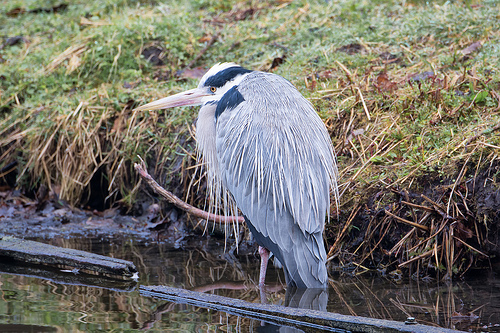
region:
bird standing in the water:
[128, 62, 340, 323]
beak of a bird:
[127, 83, 208, 126]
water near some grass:
[0, 188, 497, 331]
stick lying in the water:
[3, 225, 143, 291]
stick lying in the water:
[142, 277, 428, 332]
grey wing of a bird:
[212, 75, 340, 293]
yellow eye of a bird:
[207, 82, 219, 94]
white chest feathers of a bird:
[178, 101, 248, 256]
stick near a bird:
[133, 154, 246, 235]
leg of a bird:
[247, 243, 279, 288]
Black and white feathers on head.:
[133, 48, 273, 115]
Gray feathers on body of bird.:
[185, 46, 343, 286]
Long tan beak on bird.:
[132, 56, 261, 119]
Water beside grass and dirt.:
[1, 172, 498, 330]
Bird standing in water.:
[130, 54, 347, 306]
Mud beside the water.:
[446, 173, 498, 272]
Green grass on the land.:
[287, 9, 467, 48]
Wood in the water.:
[2, 235, 145, 287]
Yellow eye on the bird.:
[191, 58, 243, 108]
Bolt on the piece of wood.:
[398, 310, 419, 330]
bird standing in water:
[136, 59, 345, 290]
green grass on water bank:
[3, 7, 493, 291]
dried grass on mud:
[337, 169, 486, 279]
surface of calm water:
[5, 234, 498, 329]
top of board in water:
[143, 283, 448, 331]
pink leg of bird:
[253, 244, 272, 287]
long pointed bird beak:
[135, 87, 206, 120]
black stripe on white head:
[203, 62, 247, 89]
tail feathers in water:
[272, 252, 332, 298]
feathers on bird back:
[227, 75, 339, 248]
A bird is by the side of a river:
[65, 35, 456, 320]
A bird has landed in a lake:
[65, 15, 425, 305]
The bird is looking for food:
[65, 31, 426, 306]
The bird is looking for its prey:
[57, 40, 427, 315]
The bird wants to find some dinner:
[95, 25, 420, 295]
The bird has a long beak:
[75, 0, 395, 311]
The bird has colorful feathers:
[85, 26, 432, 306]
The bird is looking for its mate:
[60, 30, 405, 312]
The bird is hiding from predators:
[80, 31, 430, 301]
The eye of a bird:
[205, 80, 216, 96]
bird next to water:
[95, 25, 382, 277]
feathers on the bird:
[254, 93, 326, 192]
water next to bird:
[178, 254, 210, 279]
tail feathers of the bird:
[280, 239, 332, 301]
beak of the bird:
[131, 83, 202, 135]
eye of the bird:
[203, 76, 228, 108]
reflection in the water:
[126, 301, 160, 329]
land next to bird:
[366, 41, 429, 121]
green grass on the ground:
[321, 18, 356, 53]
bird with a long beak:
[101, 52, 358, 263]